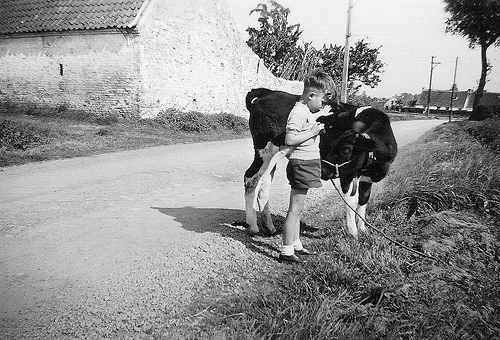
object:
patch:
[354, 106, 371, 118]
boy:
[278, 70, 336, 263]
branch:
[473, 37, 500, 111]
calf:
[244, 88, 398, 240]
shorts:
[286, 158, 324, 189]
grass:
[226, 120, 500, 335]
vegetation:
[294, 121, 499, 339]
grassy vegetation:
[255, 116, 497, 338]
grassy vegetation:
[0, 103, 250, 166]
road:
[0, 119, 468, 339]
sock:
[281, 245, 294, 256]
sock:
[293, 239, 303, 251]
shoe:
[278, 254, 308, 265]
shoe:
[294, 249, 316, 255]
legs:
[243, 148, 288, 238]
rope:
[330, 179, 445, 265]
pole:
[340, 1, 352, 103]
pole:
[426, 56, 435, 117]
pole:
[448, 56, 458, 121]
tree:
[444, 0, 499, 107]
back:
[266, 89, 370, 124]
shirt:
[286, 101, 321, 160]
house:
[2, 0, 308, 123]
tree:
[246, 0, 305, 77]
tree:
[312, 40, 386, 99]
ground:
[2, 117, 482, 336]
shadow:
[150, 206, 323, 261]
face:
[321, 135, 358, 180]